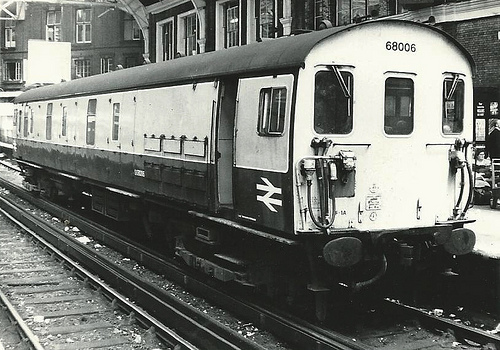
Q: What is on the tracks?
A: A train.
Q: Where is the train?
A: On the tracks.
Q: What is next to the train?
A: Buildings.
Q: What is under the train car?
A: The wheels.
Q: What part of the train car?
A: The front.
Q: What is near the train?
A: The train tracks.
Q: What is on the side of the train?
A: The door.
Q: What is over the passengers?
A: The top of the train car.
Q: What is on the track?
A: The train.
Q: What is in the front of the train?
A: Three windows.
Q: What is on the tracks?
A: The gravel and rocks.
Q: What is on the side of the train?
A: The building.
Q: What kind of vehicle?
A: Train.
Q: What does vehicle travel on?
A: Tracks.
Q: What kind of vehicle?
A: Train.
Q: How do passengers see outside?
A: Windows.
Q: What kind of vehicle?
A: Train.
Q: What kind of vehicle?
A: Train.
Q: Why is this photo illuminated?
A: Sunlight.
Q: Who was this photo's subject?
A: The train.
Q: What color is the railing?
A: Gray.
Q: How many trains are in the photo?
A: One.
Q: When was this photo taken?
A: During the day.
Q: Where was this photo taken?
A: At a train station.